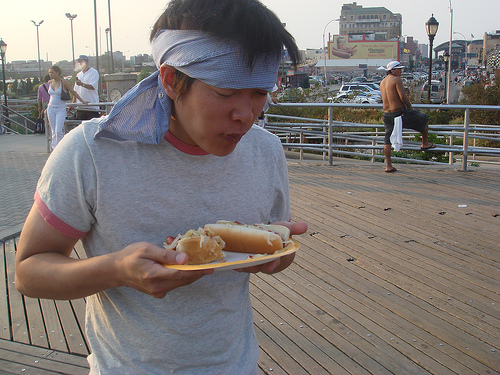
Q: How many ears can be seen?
A: 1.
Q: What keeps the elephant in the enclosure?
A: Wall.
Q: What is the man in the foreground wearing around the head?
A: Head scarf.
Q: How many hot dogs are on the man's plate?
A: Two.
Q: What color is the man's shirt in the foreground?
A: Grey and faded red.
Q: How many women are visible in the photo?
A: One.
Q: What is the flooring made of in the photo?
A: Wood.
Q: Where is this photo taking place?
A: Outdoors in the daytime.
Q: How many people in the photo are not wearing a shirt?
A: One.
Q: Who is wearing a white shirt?
A: A woman.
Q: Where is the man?
A: Boardwalk.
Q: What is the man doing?
A: Eating.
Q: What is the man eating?
A: Two hot dog.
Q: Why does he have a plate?
A: To hold his food.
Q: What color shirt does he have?
A: Gray.